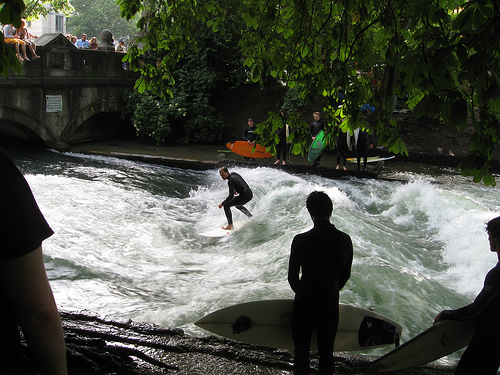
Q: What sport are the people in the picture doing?
A: Surfing.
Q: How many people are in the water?
A: One.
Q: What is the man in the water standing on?
A: Surfboard.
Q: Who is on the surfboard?
A: A man.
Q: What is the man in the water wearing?
A: Wetsuit.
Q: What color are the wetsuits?
A: Black.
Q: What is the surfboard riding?
A: A wave.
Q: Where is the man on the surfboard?
A: In the water.